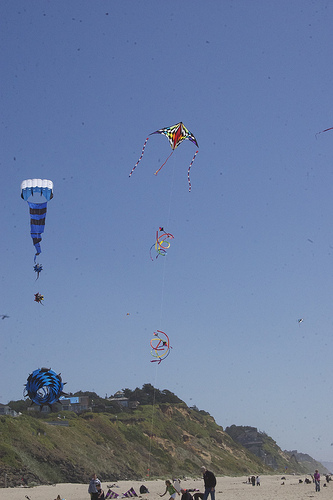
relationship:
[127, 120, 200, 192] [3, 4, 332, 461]
kite flying in sky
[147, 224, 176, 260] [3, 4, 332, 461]
kite flying in sky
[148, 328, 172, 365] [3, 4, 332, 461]
kite flying in sky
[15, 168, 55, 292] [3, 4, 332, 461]
blue kite flying in sky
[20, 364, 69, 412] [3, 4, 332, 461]
kite flying in sky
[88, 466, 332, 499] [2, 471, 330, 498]
people on beach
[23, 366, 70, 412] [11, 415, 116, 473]
kite above hill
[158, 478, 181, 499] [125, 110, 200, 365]
girl flying kite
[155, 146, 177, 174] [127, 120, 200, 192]
tail hanging from kite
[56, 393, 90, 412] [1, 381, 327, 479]
house on top hill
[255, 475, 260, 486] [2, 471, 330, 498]
people walking on beach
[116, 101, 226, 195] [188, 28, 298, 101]
airplane in sky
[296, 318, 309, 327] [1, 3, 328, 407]
airplane in sky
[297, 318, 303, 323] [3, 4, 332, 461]
airplane in sky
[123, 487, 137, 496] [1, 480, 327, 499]
kite in sand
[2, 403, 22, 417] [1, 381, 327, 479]
house on hill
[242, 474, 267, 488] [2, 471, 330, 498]
people walking on beach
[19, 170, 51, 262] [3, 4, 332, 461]
airplane in sky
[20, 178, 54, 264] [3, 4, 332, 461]
airplane in sky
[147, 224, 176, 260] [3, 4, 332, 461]
kite in sky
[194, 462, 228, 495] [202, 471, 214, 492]
man wearing shirt